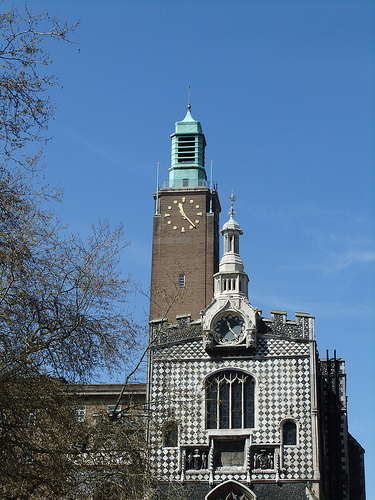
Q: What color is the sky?
A: Blue.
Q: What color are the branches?
A: Brown.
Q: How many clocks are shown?
A: Two.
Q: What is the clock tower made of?
A: Bricks.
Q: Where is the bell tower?
A: Above clock.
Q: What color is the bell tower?
A: Green.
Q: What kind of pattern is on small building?
A: Diamond.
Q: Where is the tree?
A: Front of building.